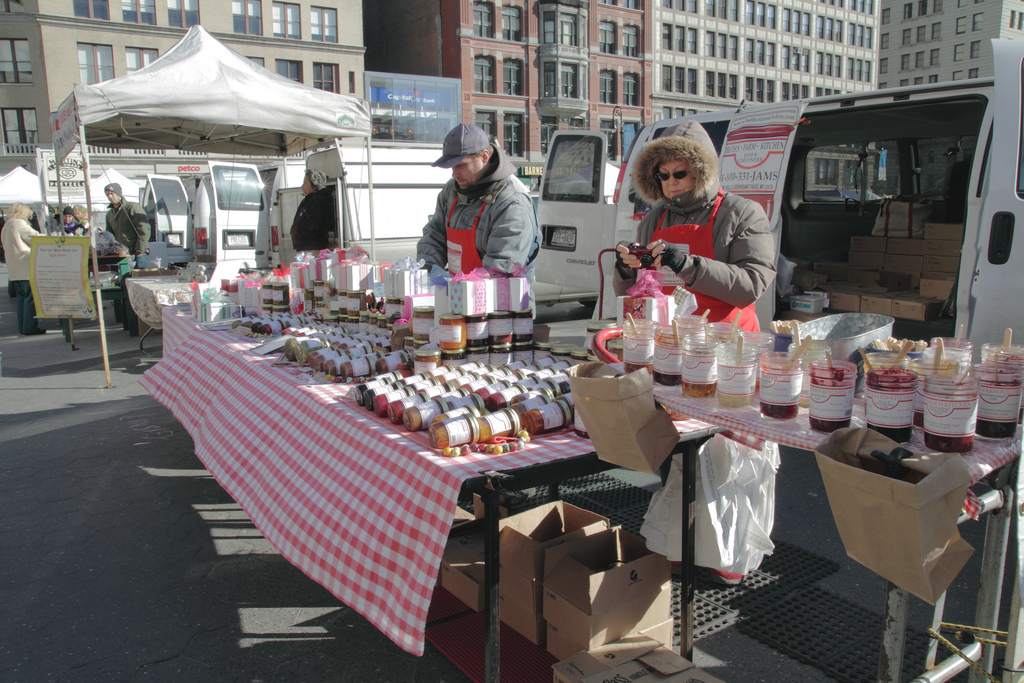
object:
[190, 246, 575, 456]
food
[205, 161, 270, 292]
door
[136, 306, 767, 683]
tablecloth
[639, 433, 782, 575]
bag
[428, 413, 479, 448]
jar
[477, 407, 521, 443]
jar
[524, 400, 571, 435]
jar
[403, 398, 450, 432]
jar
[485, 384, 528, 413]
jar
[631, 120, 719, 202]
hood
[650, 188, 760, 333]
apron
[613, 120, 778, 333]
coat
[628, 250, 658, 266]
cell phone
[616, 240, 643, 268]
hand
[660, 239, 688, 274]
hand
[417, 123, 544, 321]
man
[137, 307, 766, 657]
red/white tablecloth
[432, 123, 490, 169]
cap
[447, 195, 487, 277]
apron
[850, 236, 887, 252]
boxes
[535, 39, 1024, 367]
van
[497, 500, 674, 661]
boxes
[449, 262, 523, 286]
ribbons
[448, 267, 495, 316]
boxes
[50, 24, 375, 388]
tent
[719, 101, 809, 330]
door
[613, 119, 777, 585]
person